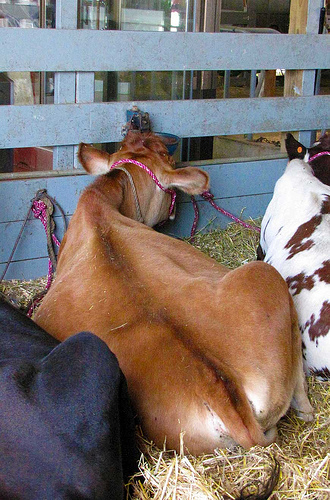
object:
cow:
[254, 129, 329, 384]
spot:
[284, 212, 323, 248]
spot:
[284, 269, 316, 296]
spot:
[307, 299, 330, 348]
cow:
[24, 123, 315, 459]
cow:
[0, 284, 142, 498]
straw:
[0, 207, 330, 500]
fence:
[0, 0, 330, 292]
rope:
[107, 158, 177, 228]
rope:
[305, 147, 330, 167]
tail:
[204, 367, 280, 459]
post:
[297, 0, 324, 150]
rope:
[112, 165, 144, 222]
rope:
[40, 195, 58, 275]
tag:
[294, 143, 304, 156]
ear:
[283, 131, 310, 164]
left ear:
[76, 139, 114, 177]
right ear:
[165, 164, 212, 198]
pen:
[0, 0, 330, 500]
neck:
[298, 149, 329, 175]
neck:
[91, 158, 159, 221]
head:
[283, 130, 330, 186]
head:
[76, 125, 211, 230]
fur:
[2, 296, 136, 497]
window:
[0, 0, 199, 178]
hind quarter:
[37, 323, 147, 491]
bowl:
[123, 107, 182, 159]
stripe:
[84, 201, 257, 420]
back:
[36, 191, 293, 459]